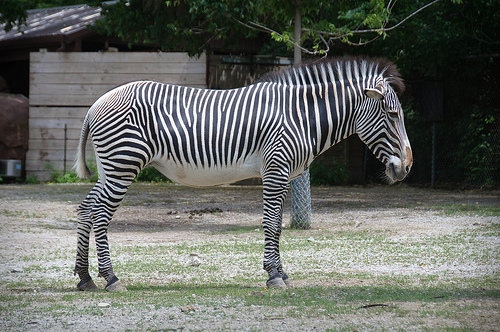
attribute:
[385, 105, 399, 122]
eye — black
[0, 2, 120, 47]
roof — slanted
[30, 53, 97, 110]
wall — wooden